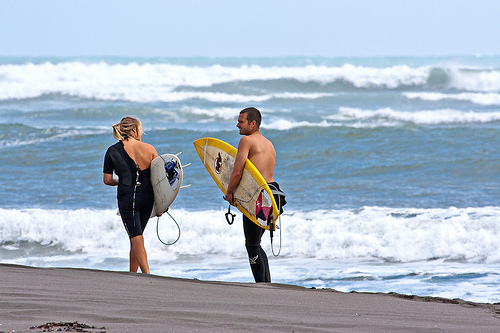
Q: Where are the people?
A: Beach.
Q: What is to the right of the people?
A: Ocean.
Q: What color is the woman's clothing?
A: Black.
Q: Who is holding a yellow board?
A: The man.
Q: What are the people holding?
A: Surfboards.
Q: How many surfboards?
A: Two.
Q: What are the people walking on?
A: Sand.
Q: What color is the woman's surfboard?
A: White.